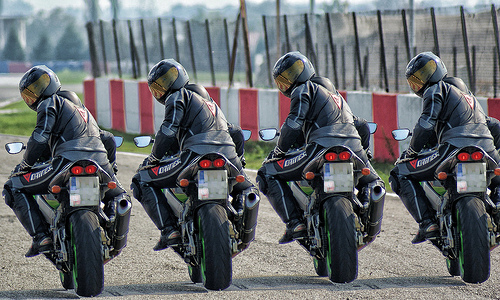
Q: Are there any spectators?
A: No, there are no spectators.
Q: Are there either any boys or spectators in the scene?
A: No, there are no spectators or boys.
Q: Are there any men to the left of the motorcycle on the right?
A: Yes, there is a man to the left of the motorbike.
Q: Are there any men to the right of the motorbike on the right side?
A: No, the man is to the left of the motorcycle.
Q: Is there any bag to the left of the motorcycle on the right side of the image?
A: No, there is a man to the left of the motorcycle.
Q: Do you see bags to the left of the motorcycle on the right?
A: No, there is a man to the left of the motorcycle.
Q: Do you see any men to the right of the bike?
A: Yes, there is a man to the right of the bike.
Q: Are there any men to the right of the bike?
A: Yes, there is a man to the right of the bike.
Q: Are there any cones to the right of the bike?
A: No, there is a man to the right of the bike.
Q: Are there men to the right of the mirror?
A: Yes, there is a man to the right of the mirror.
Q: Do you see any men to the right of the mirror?
A: Yes, there is a man to the right of the mirror.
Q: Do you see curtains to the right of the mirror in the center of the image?
A: No, there is a man to the right of the mirror.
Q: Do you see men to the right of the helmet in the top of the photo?
A: Yes, there is a man to the right of the helmet.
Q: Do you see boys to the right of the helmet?
A: No, there is a man to the right of the helmet.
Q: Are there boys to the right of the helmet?
A: No, there is a man to the right of the helmet.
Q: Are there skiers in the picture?
A: No, there are no skiers.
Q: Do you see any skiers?
A: No, there are no skiers.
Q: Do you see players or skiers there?
A: No, there are no skiers or players.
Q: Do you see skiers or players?
A: No, there are no skiers or players.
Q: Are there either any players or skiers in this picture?
A: No, there are no skiers or players.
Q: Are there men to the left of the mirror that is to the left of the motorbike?
A: Yes, there is a man to the left of the mirror.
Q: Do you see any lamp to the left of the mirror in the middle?
A: No, there is a man to the left of the mirror.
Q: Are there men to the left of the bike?
A: Yes, there is a man to the left of the bike.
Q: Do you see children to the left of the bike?
A: No, there is a man to the left of the bike.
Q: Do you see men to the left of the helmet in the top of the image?
A: Yes, there is a man to the left of the helmet.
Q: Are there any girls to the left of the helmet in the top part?
A: No, there is a man to the left of the helmet.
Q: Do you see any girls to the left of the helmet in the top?
A: No, there is a man to the left of the helmet.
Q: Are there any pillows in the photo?
A: No, there are no pillows.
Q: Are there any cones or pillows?
A: No, there are no pillows or cones.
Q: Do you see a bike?
A: Yes, there is a bike.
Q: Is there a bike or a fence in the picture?
A: Yes, there is a bike.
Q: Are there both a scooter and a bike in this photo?
A: No, there is a bike but no scooters.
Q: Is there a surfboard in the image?
A: No, there are no surfboards.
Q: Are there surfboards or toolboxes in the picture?
A: No, there are no surfboards or toolboxes.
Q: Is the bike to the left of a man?
A: Yes, the bike is to the left of a man.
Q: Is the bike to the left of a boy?
A: No, the bike is to the left of a man.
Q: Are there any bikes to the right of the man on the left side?
A: Yes, there is a bike to the right of the man.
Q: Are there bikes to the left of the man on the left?
A: No, the bike is to the right of the man.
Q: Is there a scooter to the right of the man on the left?
A: No, there is a bike to the right of the man.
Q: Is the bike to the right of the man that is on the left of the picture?
A: Yes, the bike is to the right of the man.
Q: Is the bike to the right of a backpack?
A: No, the bike is to the right of the man.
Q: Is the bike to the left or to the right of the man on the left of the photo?
A: The bike is to the right of the man.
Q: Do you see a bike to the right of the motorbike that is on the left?
A: Yes, there is a bike to the right of the motorbike.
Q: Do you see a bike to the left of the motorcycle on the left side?
A: No, the bike is to the right of the motorcycle.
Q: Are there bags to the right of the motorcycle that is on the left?
A: No, there is a bike to the right of the motorbike.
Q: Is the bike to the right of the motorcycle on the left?
A: Yes, the bike is to the right of the motorcycle.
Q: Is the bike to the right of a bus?
A: No, the bike is to the right of the motorcycle.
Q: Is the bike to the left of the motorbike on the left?
A: No, the bike is to the right of the motorcycle.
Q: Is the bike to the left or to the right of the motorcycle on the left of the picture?
A: The bike is to the right of the motorcycle.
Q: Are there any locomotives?
A: No, there are no locomotives.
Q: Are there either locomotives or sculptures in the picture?
A: No, there are no locomotives or sculptures.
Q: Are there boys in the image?
A: No, there are no boys.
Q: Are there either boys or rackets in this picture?
A: No, there are no boys or rackets.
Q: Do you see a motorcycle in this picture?
A: Yes, there are motorcycles.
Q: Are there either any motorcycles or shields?
A: Yes, there are motorcycles.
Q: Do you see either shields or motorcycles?
A: Yes, there are motorcycles.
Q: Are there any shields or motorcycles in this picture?
A: Yes, there are motorcycles.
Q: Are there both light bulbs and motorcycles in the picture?
A: No, there are motorcycles but no light bulbs.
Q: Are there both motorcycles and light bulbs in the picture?
A: No, there are motorcycles but no light bulbs.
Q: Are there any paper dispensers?
A: No, there are no paper dispensers.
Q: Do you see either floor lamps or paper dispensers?
A: No, there are no paper dispensers or floor lamps.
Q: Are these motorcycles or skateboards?
A: These are motorcycles.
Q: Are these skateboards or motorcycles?
A: These are motorcycles.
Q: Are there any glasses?
A: No, there are no glasses.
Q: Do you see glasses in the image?
A: No, there are no glasses.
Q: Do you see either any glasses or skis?
A: No, there are no glasses or skis.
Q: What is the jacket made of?
A: The jacket is made of leather.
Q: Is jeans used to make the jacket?
A: No, the jacket is made of leather.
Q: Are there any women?
A: No, there are no women.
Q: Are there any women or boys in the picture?
A: No, there are no women or boys.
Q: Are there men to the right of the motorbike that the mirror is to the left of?
A: Yes, there is a man to the right of the motorcycle.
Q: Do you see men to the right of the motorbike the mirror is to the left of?
A: Yes, there is a man to the right of the motorcycle.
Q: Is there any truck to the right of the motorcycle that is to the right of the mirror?
A: No, there is a man to the right of the motorbike.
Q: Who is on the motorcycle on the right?
A: The man is on the motorbike.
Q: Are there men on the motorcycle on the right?
A: Yes, there is a man on the motorbike.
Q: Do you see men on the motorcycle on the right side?
A: Yes, there is a man on the motorbike.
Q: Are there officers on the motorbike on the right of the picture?
A: No, there is a man on the motorcycle.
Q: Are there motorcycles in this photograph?
A: Yes, there is a motorcycle.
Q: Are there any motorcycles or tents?
A: Yes, there is a motorcycle.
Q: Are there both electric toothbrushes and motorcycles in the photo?
A: No, there is a motorcycle but no electric toothbrushes.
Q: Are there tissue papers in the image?
A: No, there are no tissue papers.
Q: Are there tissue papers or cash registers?
A: No, there are no tissue papers or cash registers.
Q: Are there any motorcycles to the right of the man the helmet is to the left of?
A: Yes, there is a motorcycle to the right of the man.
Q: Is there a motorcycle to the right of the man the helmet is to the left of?
A: Yes, there is a motorcycle to the right of the man.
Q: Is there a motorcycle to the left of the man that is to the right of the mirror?
A: No, the motorcycle is to the right of the man.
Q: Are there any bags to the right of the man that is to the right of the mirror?
A: No, there is a motorcycle to the right of the man.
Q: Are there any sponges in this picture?
A: No, there are no sponges.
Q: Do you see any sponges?
A: No, there are no sponges.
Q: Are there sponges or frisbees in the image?
A: No, there are no sponges or frisbees.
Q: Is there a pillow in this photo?
A: No, there are no pillows.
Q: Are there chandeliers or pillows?
A: No, there are no pillows or chandeliers.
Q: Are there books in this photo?
A: No, there are no books.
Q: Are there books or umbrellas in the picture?
A: No, there are no books or umbrellas.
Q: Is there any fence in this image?
A: Yes, there is a fence.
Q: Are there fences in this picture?
A: Yes, there is a fence.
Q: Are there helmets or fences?
A: Yes, there is a fence.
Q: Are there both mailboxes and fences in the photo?
A: No, there is a fence but no mailboxes.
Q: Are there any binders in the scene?
A: No, there are no binders.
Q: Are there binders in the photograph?
A: No, there are no binders.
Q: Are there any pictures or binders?
A: No, there are no binders or pictures.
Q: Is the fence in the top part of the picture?
A: Yes, the fence is in the top of the image.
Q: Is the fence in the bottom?
A: No, the fence is in the top of the image.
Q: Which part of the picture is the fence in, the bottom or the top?
A: The fence is in the top of the image.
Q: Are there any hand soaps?
A: No, there are no hand soaps.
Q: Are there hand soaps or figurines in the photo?
A: No, there are no hand soaps or figurines.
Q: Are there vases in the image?
A: No, there are no vases.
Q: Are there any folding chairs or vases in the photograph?
A: No, there are no vases or folding chairs.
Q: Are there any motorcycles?
A: Yes, there is a motorcycle.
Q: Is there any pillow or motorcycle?
A: Yes, there is a motorcycle.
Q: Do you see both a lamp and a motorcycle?
A: No, there is a motorcycle but no lamps.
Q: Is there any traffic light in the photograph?
A: No, there are no traffic lights.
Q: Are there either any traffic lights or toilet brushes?
A: No, there are no traffic lights or toilet brushes.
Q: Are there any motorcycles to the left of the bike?
A: Yes, there is a motorcycle to the left of the bike.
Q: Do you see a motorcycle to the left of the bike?
A: Yes, there is a motorcycle to the left of the bike.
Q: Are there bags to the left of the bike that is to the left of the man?
A: No, there is a motorcycle to the left of the bike.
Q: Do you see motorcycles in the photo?
A: Yes, there is a motorcycle.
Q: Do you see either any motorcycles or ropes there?
A: Yes, there is a motorcycle.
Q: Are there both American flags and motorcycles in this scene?
A: No, there is a motorcycle but no American flags.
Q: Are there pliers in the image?
A: No, there are no pliers.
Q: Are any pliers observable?
A: No, there are no pliers.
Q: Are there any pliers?
A: No, there are no pliers.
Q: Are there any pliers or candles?
A: No, there are no pliers or candles.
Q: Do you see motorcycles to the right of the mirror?
A: Yes, there is a motorcycle to the right of the mirror.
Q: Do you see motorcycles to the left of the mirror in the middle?
A: No, the motorcycle is to the right of the mirror.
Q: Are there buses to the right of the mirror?
A: No, there is a motorcycle to the right of the mirror.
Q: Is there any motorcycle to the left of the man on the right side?
A: Yes, there is a motorcycle to the left of the man.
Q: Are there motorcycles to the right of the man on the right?
A: No, the motorcycle is to the left of the man.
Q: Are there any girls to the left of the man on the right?
A: No, there is a motorcycle to the left of the man.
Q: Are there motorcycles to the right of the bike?
A: Yes, there is a motorcycle to the right of the bike.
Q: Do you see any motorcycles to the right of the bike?
A: Yes, there is a motorcycle to the right of the bike.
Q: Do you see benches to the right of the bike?
A: No, there is a motorcycle to the right of the bike.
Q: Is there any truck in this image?
A: No, there are no trucks.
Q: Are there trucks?
A: No, there are no trucks.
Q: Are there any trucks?
A: No, there are no trucks.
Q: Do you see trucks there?
A: No, there are no trucks.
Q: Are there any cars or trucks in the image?
A: No, there are no trucks or cars.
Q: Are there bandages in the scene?
A: No, there are no bandages.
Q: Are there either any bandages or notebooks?
A: No, there are no bandages or notebooks.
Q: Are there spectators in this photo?
A: No, there are no spectators.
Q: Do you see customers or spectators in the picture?
A: No, there are no spectators or customers.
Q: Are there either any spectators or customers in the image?
A: No, there are no spectators or customers.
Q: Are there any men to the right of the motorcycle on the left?
A: Yes, there is a man to the right of the motorbike.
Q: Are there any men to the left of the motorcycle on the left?
A: No, the man is to the right of the motorbike.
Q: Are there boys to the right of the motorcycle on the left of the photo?
A: No, there is a man to the right of the motorbike.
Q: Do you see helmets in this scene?
A: Yes, there is a helmet.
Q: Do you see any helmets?
A: Yes, there is a helmet.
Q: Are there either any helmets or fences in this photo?
A: Yes, there is a helmet.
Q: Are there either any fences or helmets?
A: Yes, there is a helmet.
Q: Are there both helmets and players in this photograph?
A: No, there is a helmet but no players.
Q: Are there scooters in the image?
A: No, there are no scooters.